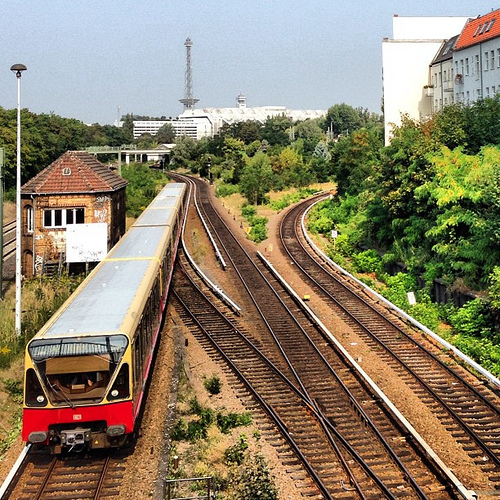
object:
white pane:
[43, 207, 85, 229]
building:
[20, 150, 130, 283]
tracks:
[0, 443, 113, 499]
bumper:
[28, 431, 47, 443]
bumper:
[106, 425, 125, 437]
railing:
[300, 195, 499, 494]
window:
[35, 354, 122, 408]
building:
[114, 36, 328, 140]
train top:
[32, 183, 187, 341]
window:
[44, 210, 51, 226]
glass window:
[136, 322, 153, 379]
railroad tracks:
[171, 171, 500, 500]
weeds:
[166, 376, 276, 493]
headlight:
[37, 395, 44, 402]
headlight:
[111, 390, 118, 397]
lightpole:
[15, 77, 21, 337]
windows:
[466, 58, 469, 74]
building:
[451, 0, 500, 106]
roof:
[451, 8, 500, 52]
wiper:
[43, 371, 75, 408]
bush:
[325, 92, 499, 379]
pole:
[10, 63, 27, 336]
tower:
[178, 36, 200, 111]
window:
[76, 208, 85, 224]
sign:
[66, 223, 108, 263]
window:
[55, 210, 62, 226]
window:
[66, 209, 73, 224]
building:
[423, 33, 461, 116]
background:
[0, 0, 500, 167]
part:
[435, 198, 445, 208]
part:
[119, 330, 147, 370]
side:
[130, 183, 189, 433]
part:
[101, 232, 117, 252]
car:
[21, 182, 188, 454]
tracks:
[171, 170, 500, 500]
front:
[21, 338, 134, 456]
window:
[147, 290, 164, 328]